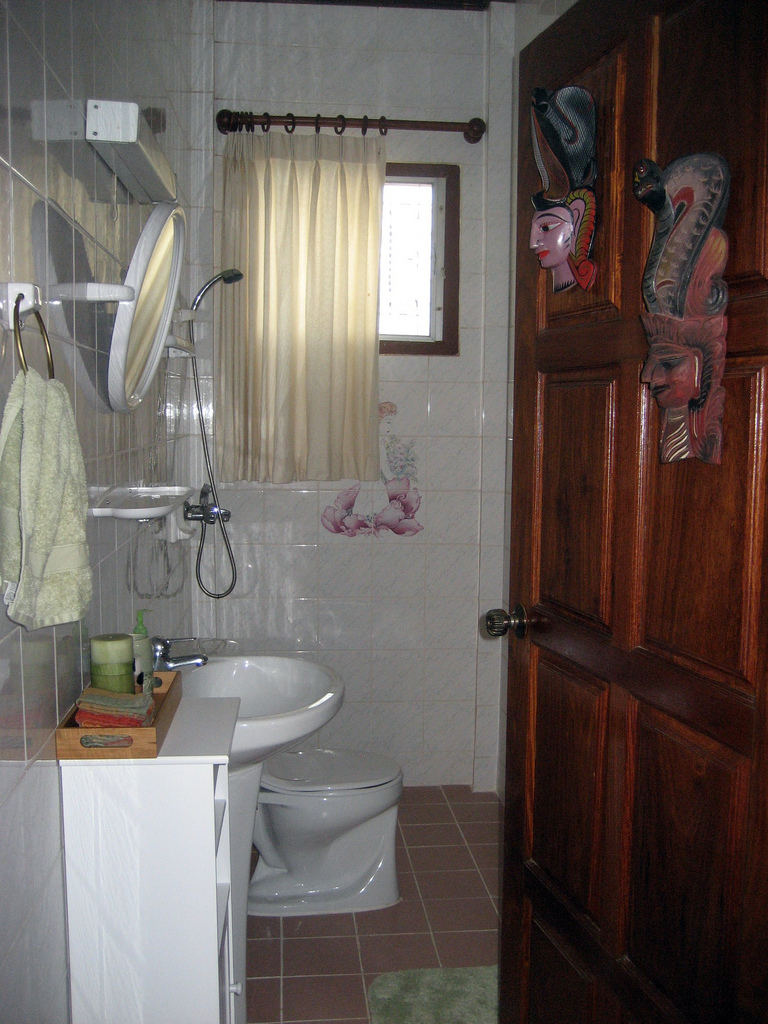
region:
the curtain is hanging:
[216, 110, 384, 484]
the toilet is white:
[164, 636, 406, 911]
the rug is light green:
[368, 964, 498, 1019]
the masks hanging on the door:
[483, 0, 764, 1017]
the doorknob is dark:
[484, 603, 526, 637]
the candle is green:
[87, 629, 137, 694]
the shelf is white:
[57, 696, 242, 1021]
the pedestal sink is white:
[148, 634, 346, 1020]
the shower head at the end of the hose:
[181, 268, 243, 600]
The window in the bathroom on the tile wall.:
[265, 168, 451, 343]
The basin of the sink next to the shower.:
[171, 645, 335, 750]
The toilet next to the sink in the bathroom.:
[228, 757, 405, 914]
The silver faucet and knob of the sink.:
[136, 625, 206, 675]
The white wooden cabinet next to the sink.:
[68, 678, 234, 1022]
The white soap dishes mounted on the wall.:
[87, 472, 194, 529]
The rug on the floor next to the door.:
[373, 959, 495, 1022]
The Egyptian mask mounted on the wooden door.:
[524, 189, 594, 300]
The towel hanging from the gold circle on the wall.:
[0, 377, 92, 638]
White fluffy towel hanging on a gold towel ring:
[2, 281, 91, 629]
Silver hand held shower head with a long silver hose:
[186, 267, 261, 600]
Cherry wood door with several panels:
[482, 4, 761, 1023]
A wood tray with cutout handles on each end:
[58, 670, 189, 756]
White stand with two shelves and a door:
[63, 696, 242, 1022]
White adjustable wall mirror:
[65, 201, 188, 417]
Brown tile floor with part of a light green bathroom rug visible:
[246, 788, 498, 1021]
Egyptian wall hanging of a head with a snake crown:
[520, 85, 595, 297]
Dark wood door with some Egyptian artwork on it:
[502, 1, 763, 1018]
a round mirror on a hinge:
[64, 200, 212, 420]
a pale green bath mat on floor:
[368, 947, 498, 1022]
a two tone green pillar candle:
[81, 626, 141, 697]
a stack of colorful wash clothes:
[59, 683, 159, 763]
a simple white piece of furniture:
[47, 687, 273, 1022]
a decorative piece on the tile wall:
[305, 388, 441, 554]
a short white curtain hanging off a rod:
[206, 90, 484, 503]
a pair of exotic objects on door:
[506, 73, 734, 498]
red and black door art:
[627, 147, 736, 465]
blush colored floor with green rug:
[242, 776, 508, 1022]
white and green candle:
[86, 630, 136, 696]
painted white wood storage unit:
[59, 696, 244, 1022]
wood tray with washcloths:
[50, 663, 186, 765]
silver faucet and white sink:
[148, 634, 349, 1022]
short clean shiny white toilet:
[243, 747, 406, 918]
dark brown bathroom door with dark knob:
[480, 3, 766, 1021]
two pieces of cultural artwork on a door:
[525, 79, 735, 468]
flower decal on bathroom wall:
[312, 396, 428, 543]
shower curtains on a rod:
[211, 95, 397, 513]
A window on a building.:
[380, 178, 461, 344]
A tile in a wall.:
[312, 597, 390, 675]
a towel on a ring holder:
[5, 279, 93, 634]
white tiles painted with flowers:
[321, 392, 426, 543]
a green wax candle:
[87, 633, 135, 694]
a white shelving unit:
[64, 699, 243, 1021]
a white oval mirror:
[82, 201, 193, 417]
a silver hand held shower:
[179, 260, 247, 604]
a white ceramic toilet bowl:
[244, 743, 401, 917]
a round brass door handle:
[478, 602, 532, 638]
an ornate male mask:
[625, 151, 731, 465]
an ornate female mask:
[520, 77, 602, 297]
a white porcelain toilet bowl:
[252, 782, 401, 912]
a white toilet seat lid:
[266, 749, 402, 793]